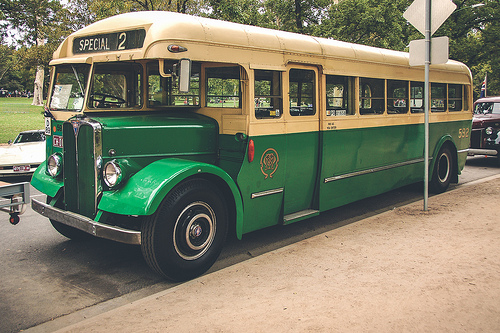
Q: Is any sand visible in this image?
A: Yes, there is sand.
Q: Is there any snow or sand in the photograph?
A: Yes, there is sand.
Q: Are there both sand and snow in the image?
A: No, there is sand but no snow.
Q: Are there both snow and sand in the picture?
A: No, there is sand but no snow.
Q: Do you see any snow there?
A: No, there is no snow.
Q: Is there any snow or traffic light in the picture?
A: No, there are no snow or traffic lights.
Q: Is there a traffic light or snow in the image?
A: No, there are no snow or traffic lights.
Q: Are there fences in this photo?
A: No, there are no fences.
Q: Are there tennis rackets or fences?
A: No, there are no fences or tennis rackets.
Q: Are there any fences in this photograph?
A: No, there are no fences.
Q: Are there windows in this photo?
A: Yes, there is a window.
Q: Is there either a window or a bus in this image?
A: Yes, there is a window.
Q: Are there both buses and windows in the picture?
A: Yes, there are both a window and a bus.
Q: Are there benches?
A: No, there are no benches.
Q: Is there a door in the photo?
A: Yes, there is a door.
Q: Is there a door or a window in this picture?
A: Yes, there is a door.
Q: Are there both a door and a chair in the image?
A: No, there is a door but no chairs.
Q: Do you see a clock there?
A: No, there are no clocks.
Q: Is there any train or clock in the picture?
A: No, there are no clocks or trains.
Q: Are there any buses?
A: Yes, there is a bus.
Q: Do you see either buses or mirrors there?
A: Yes, there is a bus.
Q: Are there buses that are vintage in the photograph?
A: Yes, there is a vintage bus.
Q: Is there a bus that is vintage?
A: Yes, there is a bus that is vintage.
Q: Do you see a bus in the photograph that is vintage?
A: Yes, there is a bus that is vintage.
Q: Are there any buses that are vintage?
A: Yes, there is a bus that is vintage.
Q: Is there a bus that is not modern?
A: Yes, there is a vintage bus.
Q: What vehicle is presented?
A: The vehicle is a bus.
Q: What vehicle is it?
A: The vehicle is a bus.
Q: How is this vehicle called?
A: That is a bus.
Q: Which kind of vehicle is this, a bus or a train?
A: That is a bus.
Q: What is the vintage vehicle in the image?
A: The vehicle is a bus.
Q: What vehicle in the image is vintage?
A: The vehicle is a bus.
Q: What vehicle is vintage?
A: The vehicle is a bus.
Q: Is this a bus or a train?
A: This is a bus.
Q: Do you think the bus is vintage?
A: Yes, the bus is vintage.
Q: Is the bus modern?
A: No, the bus is vintage.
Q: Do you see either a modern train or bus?
A: No, there is a bus but it is vintage.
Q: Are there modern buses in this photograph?
A: No, there is a bus but it is vintage.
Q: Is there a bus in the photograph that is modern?
A: No, there is a bus but it is vintage.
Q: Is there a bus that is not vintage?
A: No, there is a bus but it is vintage.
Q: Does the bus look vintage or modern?
A: The bus is vintage.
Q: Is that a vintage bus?
A: Yes, that is a vintage bus.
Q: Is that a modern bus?
A: No, that is a vintage bus.